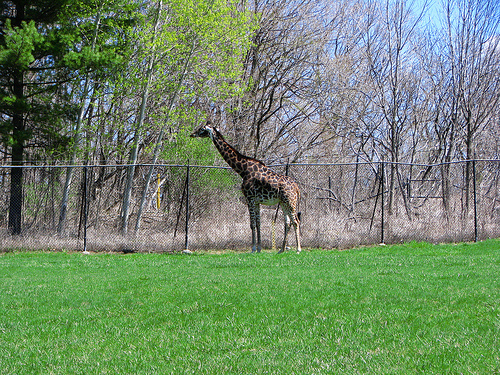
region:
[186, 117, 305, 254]
Tall giraffe standing in the grass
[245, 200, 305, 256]
Four legs on a giraffe.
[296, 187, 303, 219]
Long brown, white and black tail of a giraffe.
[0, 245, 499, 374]
Green grass on the ground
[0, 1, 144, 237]
A very green, large pine tree.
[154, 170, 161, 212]
A yellow pipe in the woods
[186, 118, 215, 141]
The head of a giraffe.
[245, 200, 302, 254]
Four legs on a tall giraffe.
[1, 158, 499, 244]
Barely visible gray chain link fence going from left to right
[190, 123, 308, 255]
A brown and white giraffe with a long neck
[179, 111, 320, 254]
giraffe eating from trees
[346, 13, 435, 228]
bare dead looking trees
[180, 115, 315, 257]
orange and brown giraffe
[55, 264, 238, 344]
bright green grass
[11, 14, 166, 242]
tall trees with leaves on them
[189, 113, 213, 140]
giraffe face by trees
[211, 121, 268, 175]
giraffe neck and mohawk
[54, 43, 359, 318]
giraffe by a bunch of trees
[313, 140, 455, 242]
enclosure fence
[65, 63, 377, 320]
giraffe on show at a zoo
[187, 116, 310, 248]
giraffe beside change link fence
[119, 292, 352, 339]
green grass in sunlight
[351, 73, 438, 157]
dead trees in photo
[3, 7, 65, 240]
tall pine tree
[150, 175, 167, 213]
yellow pole in distance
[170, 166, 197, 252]
metal poles holding fence up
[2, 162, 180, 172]
metal pole running along fence top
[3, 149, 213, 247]
change link fencing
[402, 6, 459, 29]
blue skies behind trees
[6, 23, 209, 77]
green tree leaves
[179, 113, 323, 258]
giraffe standing by himself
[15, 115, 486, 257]
giraffe standing on fence line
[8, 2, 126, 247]
tree on left side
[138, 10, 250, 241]
small sapling by big tree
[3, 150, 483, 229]
fence line behind giraffe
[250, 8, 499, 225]
trees without any leaves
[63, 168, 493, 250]
black fenceposts holding up fence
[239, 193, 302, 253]
legs of giraffe by fence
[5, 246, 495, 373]
grass giraffe is standing on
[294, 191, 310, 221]
tail of giraffe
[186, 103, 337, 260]
girrafe standing next to fence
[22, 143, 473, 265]
chain link fence next to field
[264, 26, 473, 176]
trees with no leaves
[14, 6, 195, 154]
trees with green leaves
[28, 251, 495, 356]
large field of grass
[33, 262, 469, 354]
grass is green and lush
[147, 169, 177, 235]
yellow pole behind fence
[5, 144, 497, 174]
fence has barbed wire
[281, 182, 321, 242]
giraffe has black at the end of his tail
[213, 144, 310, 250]
raffe has brown spots